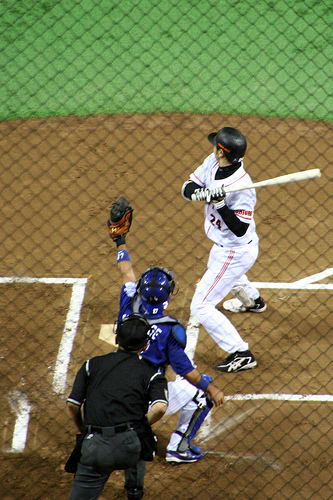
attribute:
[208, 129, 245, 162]
helmet — black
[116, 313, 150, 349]
hat — black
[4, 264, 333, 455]
markings — white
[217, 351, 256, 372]
shoes — black, white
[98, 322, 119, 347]
plate — dusty, home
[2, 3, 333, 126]
field — grassy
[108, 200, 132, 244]
glove — black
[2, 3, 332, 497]
fence — chain link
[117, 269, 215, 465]
uniform — blue, white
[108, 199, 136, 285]
catcher — reaching, crouched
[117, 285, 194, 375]
jersey — blue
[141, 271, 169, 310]
helmet — blue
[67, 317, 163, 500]
umpire — behind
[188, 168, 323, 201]
bat — hand, white, blonde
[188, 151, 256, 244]
jersey — white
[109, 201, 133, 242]
mitt — black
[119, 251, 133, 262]
armband — blue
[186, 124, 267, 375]
man — ready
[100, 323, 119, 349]
base — dirty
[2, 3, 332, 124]
grass — green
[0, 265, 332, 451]
lines — white